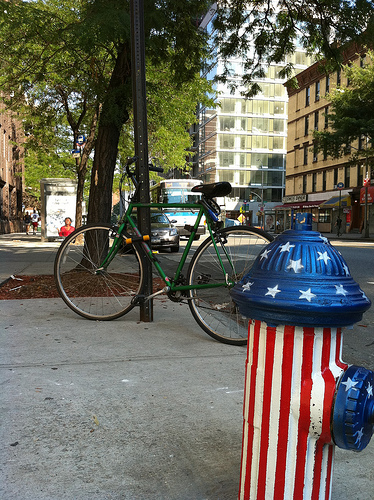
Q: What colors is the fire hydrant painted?
A: Red, white, and blue.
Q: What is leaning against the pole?
A: A bicycle.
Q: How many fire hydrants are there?
A: One.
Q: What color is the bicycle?
A: Black.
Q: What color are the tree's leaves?
A: Green.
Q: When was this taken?
A: During the day.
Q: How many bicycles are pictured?
A: One.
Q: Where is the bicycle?
A: Next to the pole.